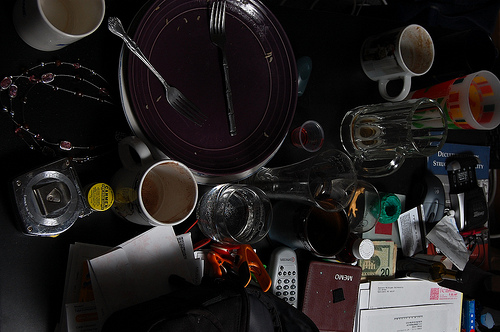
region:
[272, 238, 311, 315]
A white remote control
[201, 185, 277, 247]
A clear water glass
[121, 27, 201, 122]
A used steel spoon fork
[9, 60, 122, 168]
A beautiful necklace on the table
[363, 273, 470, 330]
Printed papers disarraged on the table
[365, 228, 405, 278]
Money on the table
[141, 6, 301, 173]
Brown used plates with fork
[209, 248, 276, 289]
Orange clips hanging from a bag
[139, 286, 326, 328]
Black bag with open zip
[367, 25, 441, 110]
white and black dirty cup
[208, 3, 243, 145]
silver metal fork on plate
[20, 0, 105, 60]
white coffee cup on table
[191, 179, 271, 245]
clear drinking glass on table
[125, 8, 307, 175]
red and white plate on table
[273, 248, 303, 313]
grey remote control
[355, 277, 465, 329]
stack of mail on table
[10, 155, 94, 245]
silver metal measuring tape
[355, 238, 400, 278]
a twenty dollar bill laying on table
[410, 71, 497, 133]
plastic cup with red and yellow design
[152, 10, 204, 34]
small pieces of rice laying on red plate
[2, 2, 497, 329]
a table filled with dishes and other items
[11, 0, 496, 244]
dirty dishes on top of a table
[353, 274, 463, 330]
mail on top of the table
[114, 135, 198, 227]
a dirty coffee cup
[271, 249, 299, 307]
a gray remote control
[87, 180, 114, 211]
Carmex treatment for dry lips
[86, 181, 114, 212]
Carmex lip balm to heal dry lips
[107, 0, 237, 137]
two forks on top of a purple plate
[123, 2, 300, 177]
an unclean purple plate on the table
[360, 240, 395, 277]
a folded twenty dollar bill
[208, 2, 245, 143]
Fork sitting on a plate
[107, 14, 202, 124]
Eating utensil sitting on a plate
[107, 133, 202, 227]
Coffee cup sitting on a table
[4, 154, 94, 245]
Tape measure sitting on a table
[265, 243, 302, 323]
Remote-control sitting on the table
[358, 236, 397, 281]
Wad of cash sitting on a table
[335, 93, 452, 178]
Beer mug sitting on a table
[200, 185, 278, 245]
Drinking glass sitting on the table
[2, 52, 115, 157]
Jewelry sitting on the table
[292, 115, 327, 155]
Shot glass sitting on a table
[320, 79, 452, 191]
a big glass with handle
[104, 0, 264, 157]
two forks over a dish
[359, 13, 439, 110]
a dirty white cup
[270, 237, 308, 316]
part of a remote control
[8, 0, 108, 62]
a white cup next to a dish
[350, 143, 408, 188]
handle of cup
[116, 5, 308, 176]
a dish color purple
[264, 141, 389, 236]
two empty glasses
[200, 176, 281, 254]
a glass with water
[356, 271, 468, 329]
white envelopes with stamps